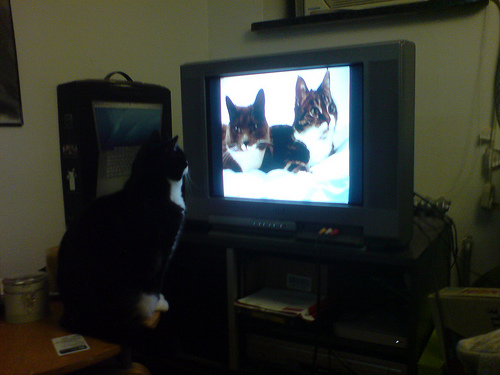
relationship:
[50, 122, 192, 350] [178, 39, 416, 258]
cat watches tv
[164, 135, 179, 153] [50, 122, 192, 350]
ear on cat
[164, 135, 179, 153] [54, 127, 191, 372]
ear on cat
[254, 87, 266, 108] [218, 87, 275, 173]
ear on cat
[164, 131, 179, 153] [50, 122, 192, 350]
ear on cat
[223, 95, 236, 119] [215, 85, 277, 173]
ear on cat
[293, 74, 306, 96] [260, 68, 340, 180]
ear on cat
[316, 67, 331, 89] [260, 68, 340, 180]
ear on cat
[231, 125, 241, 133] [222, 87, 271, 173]
eye on cat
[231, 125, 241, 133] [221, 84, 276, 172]
eye on cat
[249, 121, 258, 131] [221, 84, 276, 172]
eye on cat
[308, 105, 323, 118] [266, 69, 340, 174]
eye on cat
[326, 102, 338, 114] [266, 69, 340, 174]
eye on cat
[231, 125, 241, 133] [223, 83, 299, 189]
eye on cat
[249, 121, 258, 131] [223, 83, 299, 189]
eye on cat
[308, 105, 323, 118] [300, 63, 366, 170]
eye on cat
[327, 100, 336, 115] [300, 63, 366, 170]
eye on cat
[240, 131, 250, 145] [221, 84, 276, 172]
nose on cat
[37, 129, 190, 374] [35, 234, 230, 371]
cat perched on chair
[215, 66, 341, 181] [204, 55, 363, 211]
cats displayed on screen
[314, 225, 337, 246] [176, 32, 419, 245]
cables plugged into tv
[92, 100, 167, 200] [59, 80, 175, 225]
laptop pictured on box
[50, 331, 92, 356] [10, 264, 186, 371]
paper on table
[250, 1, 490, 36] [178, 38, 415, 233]
shelf above tv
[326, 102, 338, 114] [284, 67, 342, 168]
eye of cat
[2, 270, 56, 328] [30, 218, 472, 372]
container on table